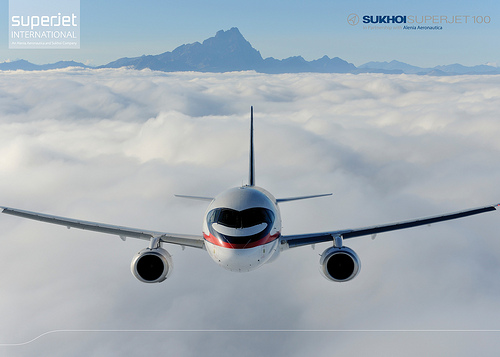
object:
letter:
[70, 11, 80, 28]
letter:
[60, 14, 71, 28]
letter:
[48, 12, 58, 30]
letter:
[30, 15, 41, 32]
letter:
[9, 13, 23, 29]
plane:
[1, 104, 500, 283]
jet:
[131, 246, 174, 284]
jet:
[316, 247, 361, 283]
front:
[201, 207, 282, 249]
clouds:
[140, 66, 152, 72]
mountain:
[0, 58, 98, 70]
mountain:
[359, 58, 500, 69]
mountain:
[310, 53, 355, 73]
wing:
[0, 205, 207, 251]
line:
[200, 232, 279, 249]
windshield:
[207, 207, 276, 229]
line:
[210, 222, 269, 237]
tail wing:
[273, 192, 334, 205]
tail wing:
[174, 193, 214, 200]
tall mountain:
[171, 26, 265, 70]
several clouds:
[0, 283, 497, 355]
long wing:
[279, 203, 499, 250]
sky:
[82, 3, 167, 50]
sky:
[1, 0, 500, 164]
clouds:
[366, 78, 404, 95]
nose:
[218, 232, 257, 265]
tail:
[247, 105, 258, 187]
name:
[361, 13, 500, 26]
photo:
[1, 2, 498, 356]